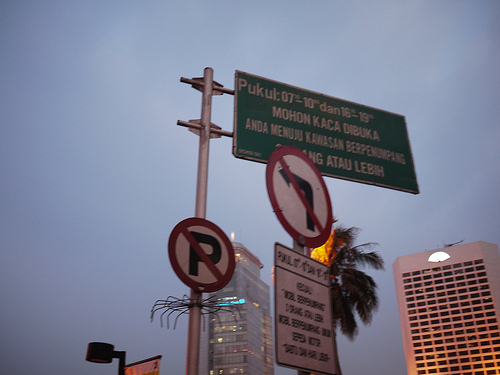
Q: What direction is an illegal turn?
A: A left turn.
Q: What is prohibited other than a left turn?
A: Parking.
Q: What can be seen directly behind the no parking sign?
A: A tall building.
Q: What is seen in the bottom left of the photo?
A: A street light.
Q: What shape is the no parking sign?
A: Circular.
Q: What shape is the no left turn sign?
A: Circular.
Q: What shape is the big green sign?
A: Rectangular.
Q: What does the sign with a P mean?
A: No parking.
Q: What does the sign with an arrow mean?
A: No left turns.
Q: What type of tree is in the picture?
A: A palm tree.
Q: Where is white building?
A: In the background on the right side of the picture.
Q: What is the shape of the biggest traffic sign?
A: Rectangle.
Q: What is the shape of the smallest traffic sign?
A: Circle.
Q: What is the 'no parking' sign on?
A: A metal pole.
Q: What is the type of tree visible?
A: A palm tree.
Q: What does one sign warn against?
A: No parking.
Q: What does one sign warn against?
A: No left turn.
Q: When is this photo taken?
A: After sunset or dusk.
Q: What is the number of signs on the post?
A: Four.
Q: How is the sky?
A: Blue with no sun.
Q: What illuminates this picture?
A: Artificial lighting for street lights.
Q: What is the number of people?
A: Zero.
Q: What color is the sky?
A: Blue.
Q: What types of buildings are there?
A: High-rises.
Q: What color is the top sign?
A: Green.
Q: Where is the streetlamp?
A: To the left of the signs.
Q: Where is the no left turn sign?
A: On a post.